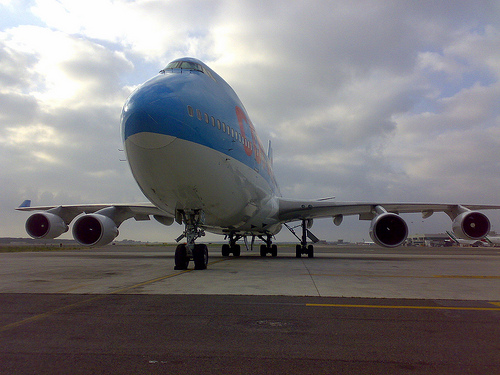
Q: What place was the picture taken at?
A: It was taken at the runway.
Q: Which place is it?
A: It is a runway.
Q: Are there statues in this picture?
A: No, there are no statues.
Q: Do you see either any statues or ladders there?
A: No, there are no statues or ladders.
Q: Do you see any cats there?
A: No, there are no cats.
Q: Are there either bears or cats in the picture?
A: No, there are no cats or bears.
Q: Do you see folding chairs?
A: No, there are no folding chairs.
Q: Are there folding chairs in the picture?
A: No, there are no folding chairs.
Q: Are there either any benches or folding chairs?
A: No, there are no folding chairs or benches.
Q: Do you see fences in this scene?
A: No, there are no fences.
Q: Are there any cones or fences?
A: No, there are no fences or cones.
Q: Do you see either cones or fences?
A: No, there are no fences or cones.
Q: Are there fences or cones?
A: No, there are no fences or cones.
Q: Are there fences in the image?
A: No, there are no fences.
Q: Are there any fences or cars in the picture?
A: No, there are no fences or cars.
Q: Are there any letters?
A: Yes, there are letters.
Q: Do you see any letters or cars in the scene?
A: Yes, there are letters.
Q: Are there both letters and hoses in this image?
A: No, there are letters but no hoses.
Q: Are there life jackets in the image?
A: No, there are no life jackets.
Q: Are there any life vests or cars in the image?
A: No, there are no life vests or cars.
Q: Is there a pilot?
A: No, there are no pilots.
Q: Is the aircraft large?
A: Yes, the aircraft is large.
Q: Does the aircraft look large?
A: Yes, the aircraft is large.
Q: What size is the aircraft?
A: The aircraft is large.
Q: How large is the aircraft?
A: The aircraft is large.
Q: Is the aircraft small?
A: No, the aircraft is large.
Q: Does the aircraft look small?
A: No, the aircraft is large.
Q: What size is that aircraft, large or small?
A: The aircraft is large.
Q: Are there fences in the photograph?
A: No, there are no fences.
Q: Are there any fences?
A: No, there are no fences.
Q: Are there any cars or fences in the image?
A: No, there are no fences or cars.